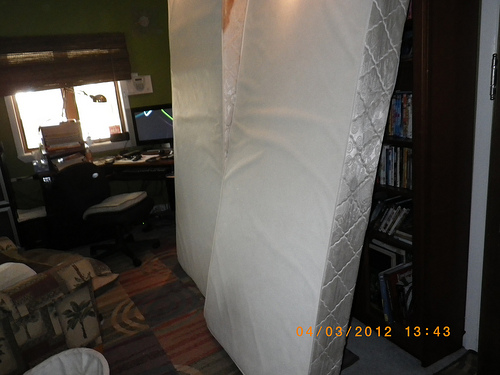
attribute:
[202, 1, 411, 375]
box spring — white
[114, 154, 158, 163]
computer keyboard — white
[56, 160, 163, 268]
computer chair — black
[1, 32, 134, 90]
window blinds — brown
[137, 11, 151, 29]
smoke detector — white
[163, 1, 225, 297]
part of mattress — big, white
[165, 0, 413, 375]
two mattresses — white, standing up